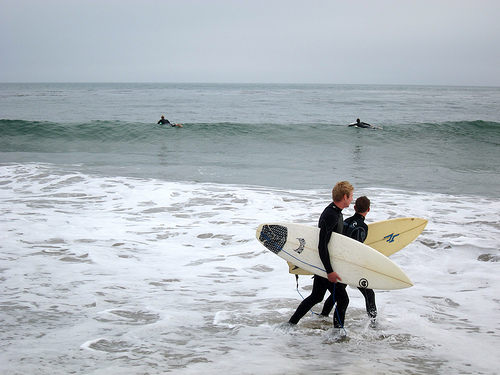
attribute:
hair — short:
[351, 189, 385, 209]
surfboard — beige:
[291, 210, 428, 277]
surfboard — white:
[250, 201, 432, 303]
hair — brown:
[353, 194, 373, 216]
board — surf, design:
[233, 202, 440, 302]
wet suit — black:
[284, 199, 346, 338]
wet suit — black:
[318, 207, 380, 325]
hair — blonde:
[314, 180, 371, 211]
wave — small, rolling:
[206, 117, 322, 144]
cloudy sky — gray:
[9, 9, 464, 84]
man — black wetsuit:
[287, 202, 349, 330]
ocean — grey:
[4, 57, 498, 342]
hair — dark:
[328, 182, 360, 214]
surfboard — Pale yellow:
[215, 197, 422, 313]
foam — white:
[1, 151, 499, 363]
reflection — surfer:
[351, 128, 365, 168]